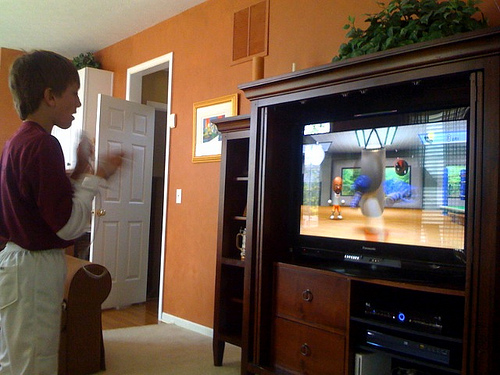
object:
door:
[87, 92, 156, 309]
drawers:
[267, 262, 351, 374]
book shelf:
[210, 116, 249, 365]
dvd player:
[356, 295, 459, 332]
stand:
[240, 24, 498, 374]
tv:
[282, 102, 469, 290]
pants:
[0, 242, 65, 372]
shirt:
[0, 120, 75, 250]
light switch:
[176, 188, 182, 202]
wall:
[0, 1, 498, 338]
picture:
[193, 100, 238, 157]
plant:
[330, 1, 492, 64]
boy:
[1, 48, 125, 375]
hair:
[6, 48, 81, 121]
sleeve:
[56, 173, 104, 242]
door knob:
[99, 209, 106, 217]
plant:
[73, 53, 102, 70]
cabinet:
[56, 65, 116, 232]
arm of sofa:
[63, 253, 111, 309]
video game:
[299, 119, 469, 249]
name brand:
[360, 245, 378, 253]